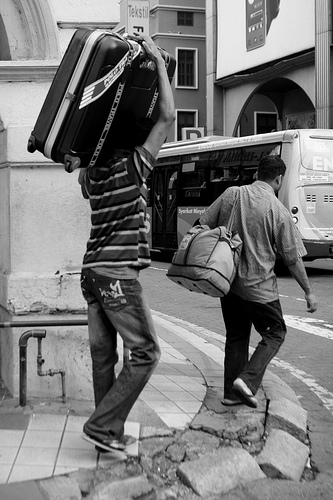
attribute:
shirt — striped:
[81, 145, 161, 269]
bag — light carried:
[165, 222, 242, 298]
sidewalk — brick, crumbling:
[30, 262, 323, 465]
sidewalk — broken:
[0, 307, 309, 498]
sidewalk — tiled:
[16, 286, 315, 493]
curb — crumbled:
[89, 423, 317, 485]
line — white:
[265, 304, 332, 355]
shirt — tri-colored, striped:
[62, 145, 182, 286]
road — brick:
[146, 260, 332, 380]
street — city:
[138, 260, 332, 499]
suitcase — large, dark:
[28, 32, 139, 146]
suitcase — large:
[6, 13, 245, 227]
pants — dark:
[71, 254, 174, 465]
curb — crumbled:
[187, 392, 302, 490]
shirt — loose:
[184, 164, 311, 311]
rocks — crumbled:
[76, 411, 264, 498]